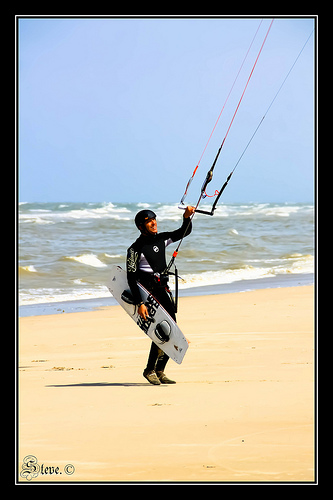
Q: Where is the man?
A: On sand.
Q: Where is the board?
A: Under man's right arm.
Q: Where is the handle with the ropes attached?
A: Left hand.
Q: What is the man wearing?
A: Wetsuit.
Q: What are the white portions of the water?
A: Waves.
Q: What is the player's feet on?
A: Sand.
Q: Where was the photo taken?
A: Beach.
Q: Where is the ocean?
A: Behind the man.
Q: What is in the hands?
A: Sailing kite cable.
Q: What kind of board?
A: Surf.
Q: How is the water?
A: Choppy.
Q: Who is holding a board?
A: The man.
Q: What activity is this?
A: Parasailing.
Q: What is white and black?
A: Board.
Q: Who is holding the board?
A: The man.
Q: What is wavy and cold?
A: Ocean.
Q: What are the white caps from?
A: Wind.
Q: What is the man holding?
A: A handle.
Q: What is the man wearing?
A: A wet suit.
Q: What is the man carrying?
A: A board.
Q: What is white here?
A: The waves.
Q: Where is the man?
A: Beach.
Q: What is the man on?
A: Sand.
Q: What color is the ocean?
A: Blue.